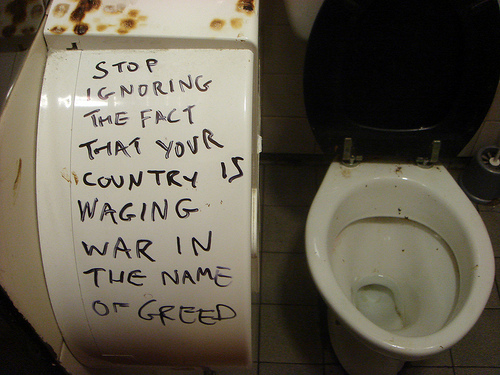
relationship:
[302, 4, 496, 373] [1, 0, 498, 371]
toilet in bathroom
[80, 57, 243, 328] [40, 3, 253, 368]
letters on dispenser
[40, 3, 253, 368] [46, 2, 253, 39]
dispenser has rust marks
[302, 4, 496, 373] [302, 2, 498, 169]
toilet has a lid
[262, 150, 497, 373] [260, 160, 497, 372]
tiles on floor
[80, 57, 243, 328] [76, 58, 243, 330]
letters about politics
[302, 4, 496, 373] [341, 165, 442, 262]
toilet has stains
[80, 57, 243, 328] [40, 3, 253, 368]
letters are on dispenser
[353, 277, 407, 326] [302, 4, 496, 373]
water in toilet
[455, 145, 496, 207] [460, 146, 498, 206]
toilet brush in a case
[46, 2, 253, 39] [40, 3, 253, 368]
rust marks on dispenser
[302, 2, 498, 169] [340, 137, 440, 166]
lid has a hinge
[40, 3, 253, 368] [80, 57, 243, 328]
dispenser has letters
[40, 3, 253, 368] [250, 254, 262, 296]
dispenser stores paper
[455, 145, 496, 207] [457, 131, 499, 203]
toilet brush in corner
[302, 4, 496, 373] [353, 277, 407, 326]
toilet has water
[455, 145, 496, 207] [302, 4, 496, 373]
toilet brush beside toilet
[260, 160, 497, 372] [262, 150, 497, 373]
floor has tiles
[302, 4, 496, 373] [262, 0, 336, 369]
toilet has shadow